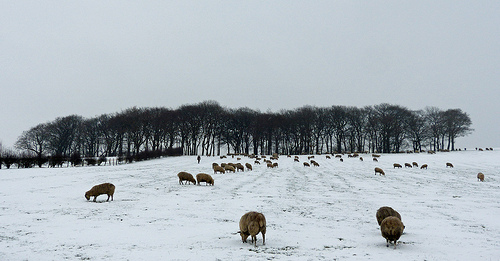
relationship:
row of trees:
[14, 100, 474, 158] [12, 104, 107, 165]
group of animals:
[212, 159, 254, 176] [177, 156, 253, 188]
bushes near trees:
[0, 145, 184, 168] [16, 100, 472, 154]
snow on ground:
[7, 151, 499, 259] [3, 151, 497, 259]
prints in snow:
[267, 170, 353, 207] [7, 151, 499, 259]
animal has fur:
[236, 212, 267, 246] [239, 210, 263, 234]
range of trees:
[14, 100, 474, 158] [16, 100, 472, 154]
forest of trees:
[14, 100, 474, 158] [12, 104, 107, 165]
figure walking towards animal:
[195, 155, 201, 161] [236, 212, 267, 246]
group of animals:
[249, 151, 320, 168] [246, 155, 327, 167]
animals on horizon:
[403, 146, 497, 154] [3, 148, 498, 160]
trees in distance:
[12, 104, 107, 165] [3, 125, 496, 162]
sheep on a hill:
[302, 155, 390, 179] [23, 137, 499, 199]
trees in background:
[16, 100, 472, 154] [2, 95, 499, 185]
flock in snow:
[68, 142, 497, 244] [7, 151, 499, 259]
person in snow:
[196, 155, 201, 165] [7, 151, 499, 259]